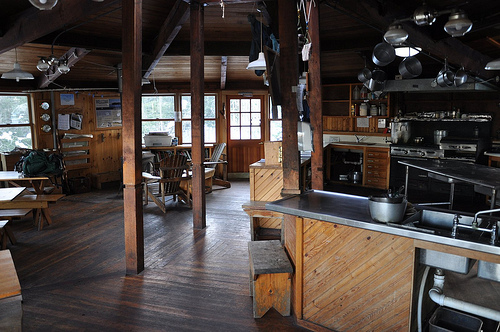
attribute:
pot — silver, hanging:
[433, 58, 455, 88]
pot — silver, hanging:
[450, 64, 469, 87]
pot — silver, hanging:
[369, 37, 397, 68]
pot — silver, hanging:
[397, 42, 423, 78]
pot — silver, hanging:
[355, 66, 372, 82]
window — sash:
[0, 94, 35, 154]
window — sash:
[139, 96, 174, 149]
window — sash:
[177, 92, 218, 145]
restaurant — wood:
[3, 3, 497, 328]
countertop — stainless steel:
[261, 186, 421, 231]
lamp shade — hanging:
[1, 40, 33, 82]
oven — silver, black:
[389, 143, 445, 197]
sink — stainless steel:
[408, 203, 498, 248]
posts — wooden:
[115, 7, 211, 278]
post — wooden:
[116, 2, 149, 275]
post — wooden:
[182, 1, 208, 233]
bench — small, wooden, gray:
[243, 235, 300, 284]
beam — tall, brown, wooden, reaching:
[80, 30, 219, 282]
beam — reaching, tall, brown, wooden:
[162, 25, 241, 273]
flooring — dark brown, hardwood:
[31, 178, 218, 327]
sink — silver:
[393, 194, 473, 253]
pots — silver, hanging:
[355, 22, 417, 65]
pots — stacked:
[346, 185, 427, 245]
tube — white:
[409, 276, 491, 322]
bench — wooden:
[227, 235, 317, 319]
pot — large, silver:
[385, 123, 434, 161]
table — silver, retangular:
[387, 147, 498, 221]